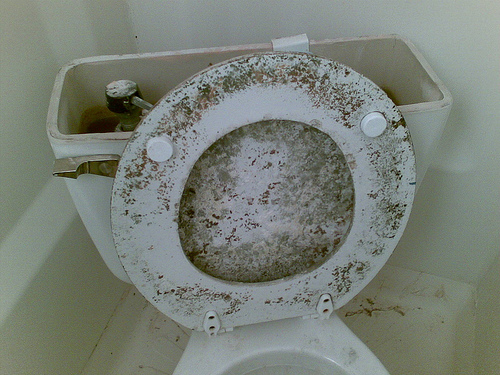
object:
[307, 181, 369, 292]
dots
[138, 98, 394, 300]
grime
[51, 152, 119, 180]
spots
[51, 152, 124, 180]
lever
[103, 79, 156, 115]
cap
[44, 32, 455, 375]
toilet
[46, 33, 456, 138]
tank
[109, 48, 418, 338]
seat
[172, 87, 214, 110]
stains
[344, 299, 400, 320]
stains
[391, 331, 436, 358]
floor